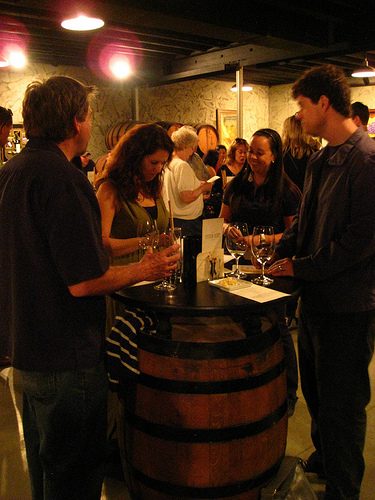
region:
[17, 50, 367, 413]
Group of people drinking wine.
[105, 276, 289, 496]
Table made out of a barrel.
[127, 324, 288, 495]
Black rings on barrel table.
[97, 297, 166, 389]
Black and white towel.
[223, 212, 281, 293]
Two wine glasses on the right.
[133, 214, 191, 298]
Two wine glasses on the left.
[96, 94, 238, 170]
Barrels stacked against wall.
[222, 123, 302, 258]
Woman on right with long dark hair.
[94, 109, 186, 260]
Woman on left with long dark hair.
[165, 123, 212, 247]
Older woman with white hair.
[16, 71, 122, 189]
Brown hair on a man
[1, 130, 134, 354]
Black shirt on a man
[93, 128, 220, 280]
Green shirt on a woman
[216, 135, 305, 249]
Woman with brown hair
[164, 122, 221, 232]
Woman with a white shirt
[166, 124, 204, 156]
Gray hair on a woman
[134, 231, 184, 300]
Wine glass in a hand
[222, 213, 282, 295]
Two wine glasses on a table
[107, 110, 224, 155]
Barrels along a wall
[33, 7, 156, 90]
Lights on a ceiling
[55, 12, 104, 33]
light on the ceiling.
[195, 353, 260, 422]
large barrel on the ground.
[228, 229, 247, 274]
clear glass on the barrel.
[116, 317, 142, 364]
striped shirt on the barrel.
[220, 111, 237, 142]
painting on the wall.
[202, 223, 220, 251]
menu on the barrel.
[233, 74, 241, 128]
support beam in the room.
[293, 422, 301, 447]
concrete on the floor.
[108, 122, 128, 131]
barrel on the wall.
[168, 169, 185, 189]
white shirt on woman.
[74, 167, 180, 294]
People are sipping wine.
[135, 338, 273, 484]
The barrel is made like a table.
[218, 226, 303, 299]
Wine glasses sitting on top of the barrel.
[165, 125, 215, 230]
A lady reading the menu.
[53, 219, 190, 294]
A man is holding a wine glass.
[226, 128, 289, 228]
The lady is laughing.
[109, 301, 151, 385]
A black and white shirt on the table.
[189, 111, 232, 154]
A clock is on the wall.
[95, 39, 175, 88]
The lights are bright and shiny.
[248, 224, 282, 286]
wine glass on table top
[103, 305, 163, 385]
striped piece of clothing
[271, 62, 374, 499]
man in a dark colored jacket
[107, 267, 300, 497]
wooden barrel table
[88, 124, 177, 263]
woman with dark colored hair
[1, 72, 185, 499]
man holding a wine glass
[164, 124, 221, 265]
woman with white shirt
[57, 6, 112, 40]
overhead light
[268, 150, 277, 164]
woman's earring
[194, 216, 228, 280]
paper with words printed on it